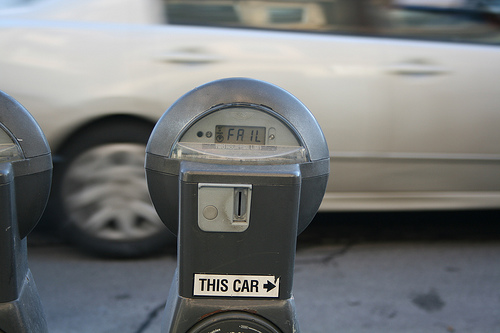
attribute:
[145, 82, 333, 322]
parking meter — grey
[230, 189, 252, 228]
coin slot — skinny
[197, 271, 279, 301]
sticker — black, white, torn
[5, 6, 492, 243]
car — silver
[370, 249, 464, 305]
road — small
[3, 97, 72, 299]
parking meter — half